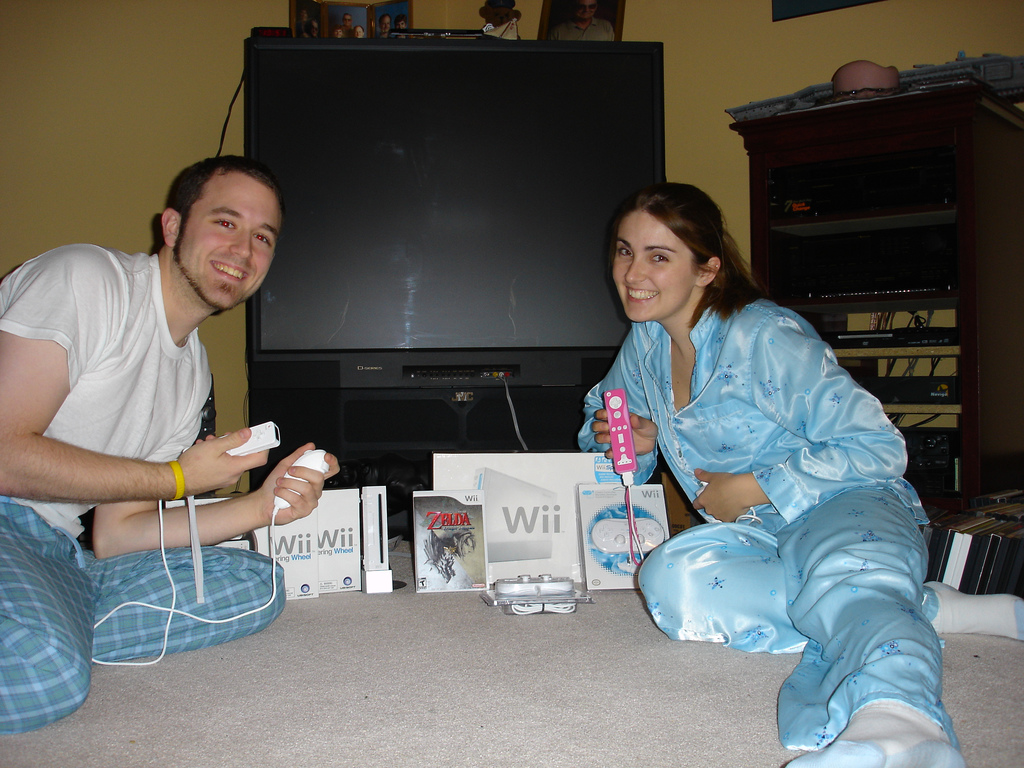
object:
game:
[413, 488, 484, 593]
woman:
[577, 179, 973, 768]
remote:
[600, 389, 638, 487]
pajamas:
[576, 299, 970, 768]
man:
[3, 157, 342, 744]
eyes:
[214, 219, 239, 232]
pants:
[2, 503, 289, 735]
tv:
[244, 29, 669, 367]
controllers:
[494, 573, 576, 615]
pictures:
[282, 1, 644, 54]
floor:
[0, 531, 1024, 768]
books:
[932, 514, 1024, 595]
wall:
[2, 4, 1024, 422]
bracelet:
[168, 461, 184, 501]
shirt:
[9, 234, 234, 544]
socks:
[788, 699, 980, 768]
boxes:
[160, 486, 389, 599]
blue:
[746, 365, 815, 409]